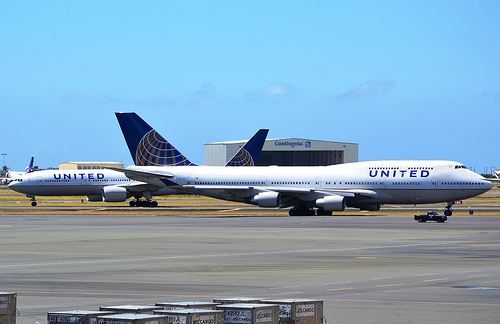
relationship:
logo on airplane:
[367, 167, 430, 179] [114, 76, 499, 266]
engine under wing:
[305, 193, 345, 211] [262, 185, 357, 198]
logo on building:
[272, 139, 312, 151] [201, 132, 364, 167]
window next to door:
[438, 179, 449, 186] [421, 170, 435, 191]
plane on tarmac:
[114, 103, 494, 228] [3, 212, 497, 317]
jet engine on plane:
[246, 189, 343, 214] [99, 110, 494, 219]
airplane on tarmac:
[201, 136, 360, 172] [3, 212, 497, 317]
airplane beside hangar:
[201, 136, 360, 172] [198, 134, 361, 176]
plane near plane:
[3, 152, 173, 208] [99, 110, 494, 219]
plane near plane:
[99, 110, 494, 219] [3, 152, 173, 208]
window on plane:
[388, 180, 403, 186] [103, 97, 495, 237]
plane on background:
[124, 106, 478, 233] [9, 105, 497, 215]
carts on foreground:
[41, 297, 327, 321] [4, 281, 498, 323]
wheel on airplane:
[442, 202, 456, 219] [105, 111, 494, 218]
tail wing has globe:
[111, 109, 203, 166] [230, 148, 254, 168]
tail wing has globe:
[221, 125, 270, 166] [134, 129, 188, 161]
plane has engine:
[106, 93, 497, 257] [279, 174, 354, 229]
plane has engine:
[99, 110, 494, 219] [248, 190, 282, 207]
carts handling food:
[41, 288, 327, 321] [72, 308, 279, 322]